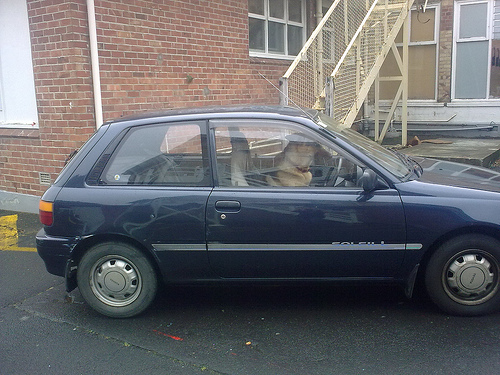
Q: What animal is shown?
A: A dog.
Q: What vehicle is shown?
A: A car.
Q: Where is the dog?
A: In the car.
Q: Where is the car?
A: On the street.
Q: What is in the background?
A: A building.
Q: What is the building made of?
A: Brick.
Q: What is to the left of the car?
A: Stairs.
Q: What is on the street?
A: The car.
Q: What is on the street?
A: The car.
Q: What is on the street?
A: The car.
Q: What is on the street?
A: The car.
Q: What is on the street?
A: The car.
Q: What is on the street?
A: The car.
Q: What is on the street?
A: The car.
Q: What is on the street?
A: The car.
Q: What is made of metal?
A: Railing.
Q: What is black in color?
A: The ground.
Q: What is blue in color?
A: The car.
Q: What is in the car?
A: A dog.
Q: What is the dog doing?
A: Sitting in the car.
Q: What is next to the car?
A: A building.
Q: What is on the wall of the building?
A: Bricks.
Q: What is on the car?
A: A door.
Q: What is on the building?
A: Windows.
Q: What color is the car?
A: Blue.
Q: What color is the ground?
A: Black.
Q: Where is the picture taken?
A: On the street.